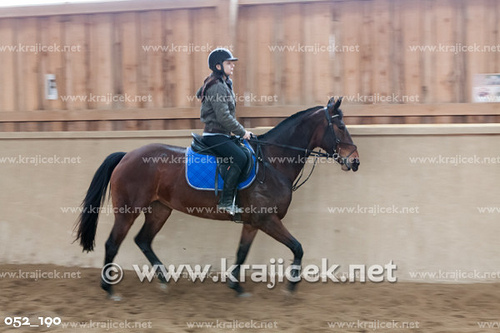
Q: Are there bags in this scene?
A: No, there are no bags.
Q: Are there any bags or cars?
A: No, there are no bags or cars.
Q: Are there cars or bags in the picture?
A: No, there are no bags or cars.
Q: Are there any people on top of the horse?
A: Yes, there is a person on top of the horse.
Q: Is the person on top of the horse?
A: Yes, the person is on top of the horse.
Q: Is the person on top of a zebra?
A: No, the person is on top of the horse.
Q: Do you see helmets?
A: Yes, there is a helmet.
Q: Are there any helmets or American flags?
A: Yes, there is a helmet.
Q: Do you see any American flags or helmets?
A: Yes, there is a helmet.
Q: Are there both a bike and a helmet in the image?
A: No, there is a helmet but no bikes.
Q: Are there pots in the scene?
A: No, there are no pots.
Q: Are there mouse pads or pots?
A: No, there are no pots or mouse pads.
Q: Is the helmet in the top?
A: Yes, the helmet is in the top of the image.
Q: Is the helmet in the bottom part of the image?
A: No, the helmet is in the top of the image.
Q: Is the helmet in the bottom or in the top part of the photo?
A: The helmet is in the top of the image.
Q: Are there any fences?
A: Yes, there is a fence.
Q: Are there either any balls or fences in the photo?
A: Yes, there is a fence.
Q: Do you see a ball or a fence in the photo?
A: Yes, there is a fence.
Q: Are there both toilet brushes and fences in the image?
A: No, there is a fence but no toilet brushes.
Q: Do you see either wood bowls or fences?
A: Yes, there is a wood fence.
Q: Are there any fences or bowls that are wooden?
A: Yes, the fence is wooden.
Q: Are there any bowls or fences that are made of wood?
A: Yes, the fence is made of wood.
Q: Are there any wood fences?
A: Yes, there is a wood fence.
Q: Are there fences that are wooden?
A: Yes, there is a fence that is wooden.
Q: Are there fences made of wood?
A: Yes, there is a fence that is made of wood.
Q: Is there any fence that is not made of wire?
A: Yes, there is a fence that is made of wood.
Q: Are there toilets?
A: No, there are no toilets.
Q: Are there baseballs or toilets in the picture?
A: No, there are no toilets or baseballs.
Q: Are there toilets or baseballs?
A: No, there are no toilets or baseballs.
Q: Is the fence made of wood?
A: Yes, the fence is made of wood.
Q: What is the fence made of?
A: The fence is made of wood.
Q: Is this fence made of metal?
A: No, the fence is made of wood.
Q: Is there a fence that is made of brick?
A: No, there is a fence but it is made of wood.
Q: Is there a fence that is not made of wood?
A: No, there is a fence but it is made of wood.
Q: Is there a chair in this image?
A: No, there are no chairs.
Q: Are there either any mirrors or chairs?
A: No, there are no chairs or mirrors.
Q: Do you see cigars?
A: No, there are no cigars.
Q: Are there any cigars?
A: No, there are no cigars.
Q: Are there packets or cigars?
A: No, there are no cigars or packets.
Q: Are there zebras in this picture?
A: No, there are no zebras.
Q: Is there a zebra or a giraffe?
A: No, there are no zebras or giraffes.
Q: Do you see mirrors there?
A: No, there are no mirrors.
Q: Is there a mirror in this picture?
A: No, there are no mirrors.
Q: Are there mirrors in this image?
A: No, there are no mirrors.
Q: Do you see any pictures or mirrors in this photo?
A: No, there are no mirrors or pictures.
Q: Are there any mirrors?
A: No, there are no mirrors.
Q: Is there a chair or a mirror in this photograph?
A: No, there are no mirrors or chairs.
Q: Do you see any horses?
A: Yes, there is a horse.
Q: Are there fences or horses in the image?
A: Yes, there is a horse.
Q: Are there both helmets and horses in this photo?
A: Yes, there are both a horse and a helmet.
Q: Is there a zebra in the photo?
A: No, there are no zebras.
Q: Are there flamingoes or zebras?
A: No, there are no zebras or flamingoes.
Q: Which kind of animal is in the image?
A: The animal is a horse.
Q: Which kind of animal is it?
A: The animal is a horse.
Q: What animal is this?
A: This is a horse.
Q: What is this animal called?
A: This is a horse.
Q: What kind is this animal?
A: This is a horse.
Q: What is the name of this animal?
A: This is a horse.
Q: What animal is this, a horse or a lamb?
A: This is a horse.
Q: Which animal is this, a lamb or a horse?
A: This is a horse.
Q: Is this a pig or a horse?
A: This is a horse.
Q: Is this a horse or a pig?
A: This is a horse.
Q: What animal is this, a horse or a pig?
A: This is a horse.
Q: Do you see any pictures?
A: No, there are no pictures.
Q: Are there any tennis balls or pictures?
A: No, there are no pictures or tennis balls.